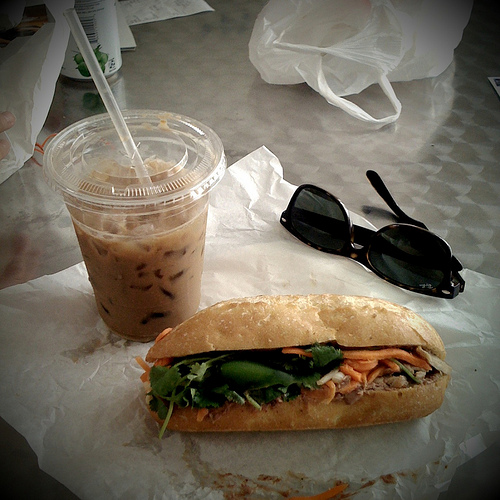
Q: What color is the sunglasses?
A: Black.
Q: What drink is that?
A: Coffee.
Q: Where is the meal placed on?
A: A table.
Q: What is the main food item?
A: Sandwich.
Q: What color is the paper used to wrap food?
A: White.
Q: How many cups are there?
A: 1.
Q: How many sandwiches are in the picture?
A: 1.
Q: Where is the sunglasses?
A: On the table.